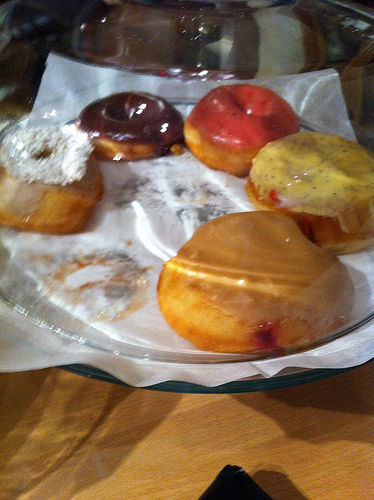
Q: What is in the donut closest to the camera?
A: Jelly.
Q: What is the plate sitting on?
A: A table.